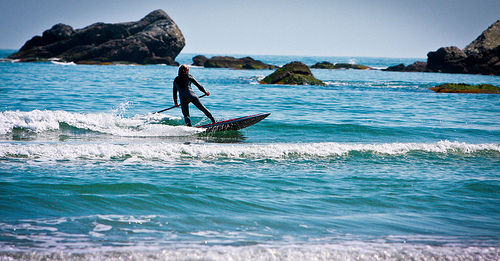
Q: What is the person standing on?
A: A board.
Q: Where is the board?
A: In the water.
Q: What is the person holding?
A: Paddle.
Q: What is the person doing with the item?
A: Rowing.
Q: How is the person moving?
A: Paddling.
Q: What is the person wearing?
A: Wetsuit.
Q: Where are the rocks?
A: In the water.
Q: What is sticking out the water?
A: Rocks.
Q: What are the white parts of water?
A: Waves.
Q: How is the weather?
A: Clear.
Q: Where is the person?
A: On the paddle board.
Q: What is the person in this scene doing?
A: Riding a paddle board.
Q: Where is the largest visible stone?
A: The upper left corner.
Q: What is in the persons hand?
A: A paddle.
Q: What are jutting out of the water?
A: Rocks.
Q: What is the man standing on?
A: Surfboard.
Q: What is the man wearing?
A: Wetsuit.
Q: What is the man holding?
A: Paddle.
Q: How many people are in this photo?
A: One.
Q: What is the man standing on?
A: Surfboard.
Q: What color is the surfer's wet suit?
A: Black.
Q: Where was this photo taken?
A: Ocean.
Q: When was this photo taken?
A: Outdoors.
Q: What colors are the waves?
A: Blue, white.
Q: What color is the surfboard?
A: Black.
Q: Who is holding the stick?
A: Surfer.